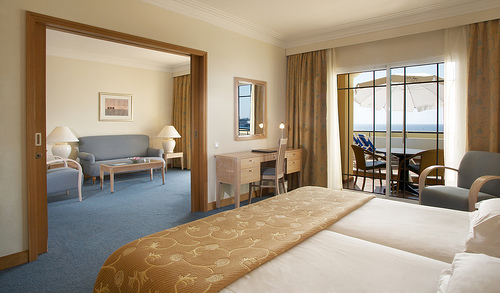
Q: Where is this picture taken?
A: Bedroom.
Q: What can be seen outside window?
A: Unbrella.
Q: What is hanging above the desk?
A: Mirror.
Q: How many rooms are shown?
A: Two.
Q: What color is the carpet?
A: Blue.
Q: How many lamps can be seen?
A: Two.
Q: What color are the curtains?
A: Tan.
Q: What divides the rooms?
A: Partition.